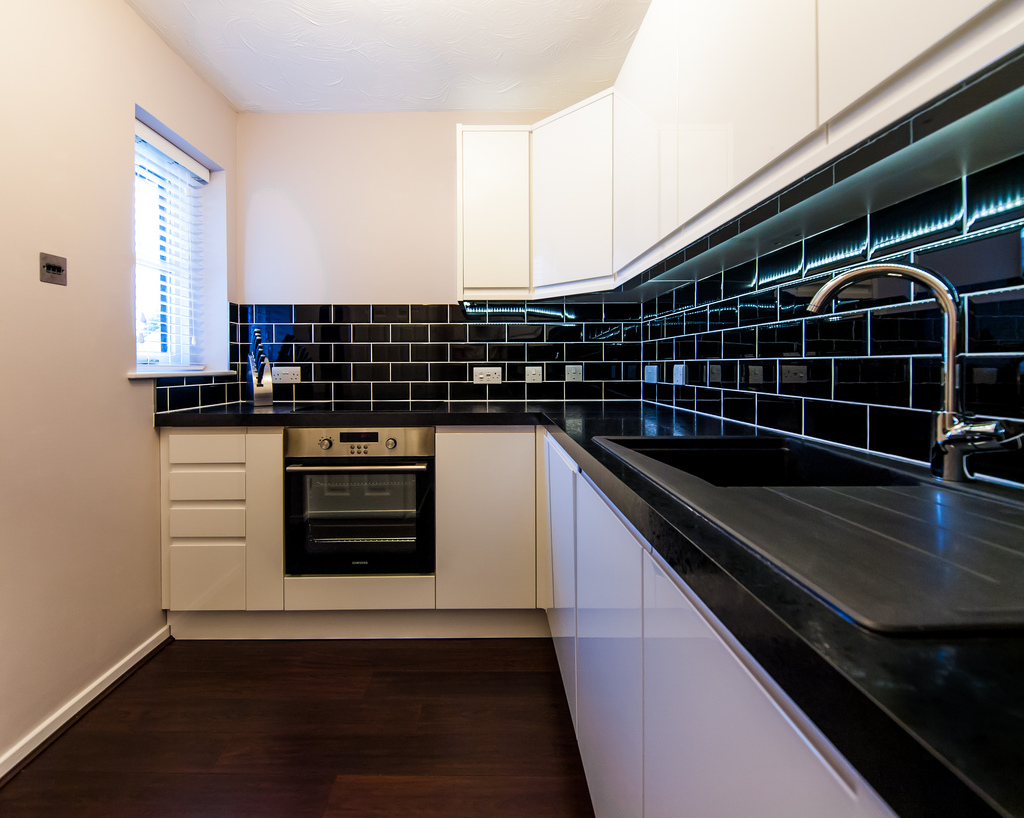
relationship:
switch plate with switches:
[35, 248, 73, 284] [42, 260, 66, 273]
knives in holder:
[245, 311, 277, 385] [244, 354, 277, 411]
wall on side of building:
[235, 106, 464, 302] [14, 0, 1010, 800]